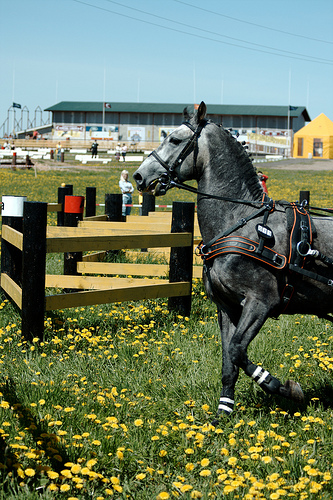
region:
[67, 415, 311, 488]
the flowers are yellow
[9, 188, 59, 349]
the fence post is black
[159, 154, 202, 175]
the bridal is black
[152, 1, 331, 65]
the wires are long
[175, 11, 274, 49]
the wires are thin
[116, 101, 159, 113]
the roof is green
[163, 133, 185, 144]
the horse has an eye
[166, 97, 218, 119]
the horse has an ear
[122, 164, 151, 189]
the horse has a nose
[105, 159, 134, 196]
the woman is standing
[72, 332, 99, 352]
weeds in the grass.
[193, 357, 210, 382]
grass on the ground.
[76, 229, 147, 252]
wooden part of fence.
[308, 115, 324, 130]
yellow tent near the building.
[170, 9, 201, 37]
wires in the air.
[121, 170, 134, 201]
woman standing in the grass.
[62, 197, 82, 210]
red paint on the post.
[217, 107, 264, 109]
green roof of building.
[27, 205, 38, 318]
black corner post of fence.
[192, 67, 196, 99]
tall white post.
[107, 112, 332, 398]
the gray horse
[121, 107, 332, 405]
the horse is trotting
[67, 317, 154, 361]
the flowers in the green grass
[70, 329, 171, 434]
the grass is uncut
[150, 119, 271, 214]
the bridal on the horse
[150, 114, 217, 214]
the bridal is black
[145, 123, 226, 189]
the bridal is leather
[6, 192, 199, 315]
the horse beside the corner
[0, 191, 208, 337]
the corner is made of wood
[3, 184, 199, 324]
the corner is black and tan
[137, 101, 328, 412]
this is a horse statue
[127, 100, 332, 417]
the statue is black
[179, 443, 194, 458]
this is a yellow flower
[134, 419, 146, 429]
this is a yellow flower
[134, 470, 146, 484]
this is a yellow flower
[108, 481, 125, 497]
this is a yellow flower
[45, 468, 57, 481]
this is a yellow flower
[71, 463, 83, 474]
this is a yellow flower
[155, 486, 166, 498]
this is a yellow flower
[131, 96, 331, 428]
Horse is gray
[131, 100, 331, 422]
Horse stepping on green grass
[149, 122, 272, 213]
Black harness on horse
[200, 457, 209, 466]
Flower is yellow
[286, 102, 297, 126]
Blue flag by yellow building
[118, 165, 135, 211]
Woman standing is wearing blue jeans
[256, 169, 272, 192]
Woman in red taking picture of horse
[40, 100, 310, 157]
Large green building by yellow building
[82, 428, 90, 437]
Flower is yellow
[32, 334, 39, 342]
Yellow flower by wooden post